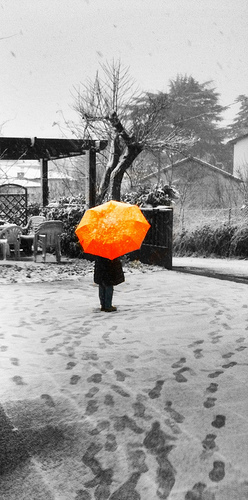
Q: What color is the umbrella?
A: Orange.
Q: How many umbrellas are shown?
A: One.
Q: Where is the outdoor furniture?
A: On patio.